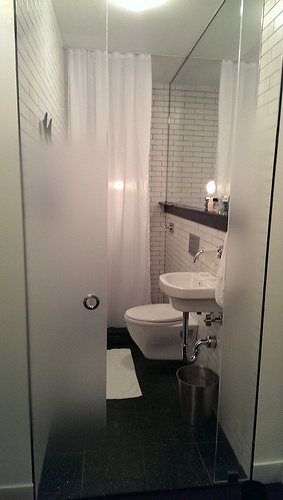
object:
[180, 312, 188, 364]
pipe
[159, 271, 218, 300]
sink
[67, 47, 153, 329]
curtain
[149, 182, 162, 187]
tile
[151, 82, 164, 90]
tile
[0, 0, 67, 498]
wall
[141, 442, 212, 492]
tiles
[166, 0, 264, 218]
mirror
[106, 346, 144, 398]
towel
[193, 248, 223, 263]
faucet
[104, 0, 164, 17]
light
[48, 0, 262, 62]
ceiling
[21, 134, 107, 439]
fogged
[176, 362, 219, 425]
can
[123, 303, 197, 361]
toilet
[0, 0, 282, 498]
reflection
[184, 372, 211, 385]
trash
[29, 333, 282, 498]
floor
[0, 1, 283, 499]
bathroom